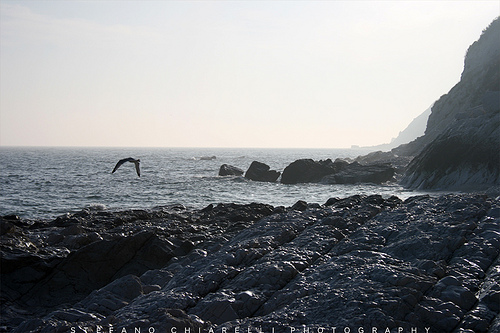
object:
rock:
[2, 193, 500, 333]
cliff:
[391, 17, 499, 189]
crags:
[398, 40, 498, 190]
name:
[70, 326, 430, 333]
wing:
[135, 162, 141, 177]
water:
[0, 146, 464, 220]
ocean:
[1, 145, 457, 217]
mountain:
[350, 0, 500, 189]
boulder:
[217, 163, 243, 175]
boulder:
[244, 161, 281, 182]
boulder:
[322, 165, 394, 184]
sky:
[2, 1, 499, 146]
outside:
[0, 0, 500, 328]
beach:
[2, 185, 499, 331]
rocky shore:
[2, 190, 500, 330]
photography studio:
[70, 326, 432, 333]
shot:
[3, 0, 500, 333]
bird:
[112, 157, 140, 177]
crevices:
[251, 212, 377, 317]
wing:
[112, 157, 129, 173]